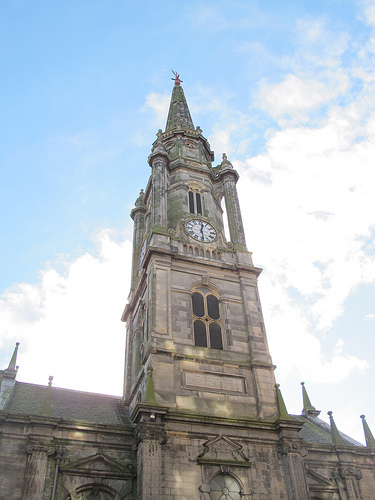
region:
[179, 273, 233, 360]
tower window is black and gold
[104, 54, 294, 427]
Pointy tower on a building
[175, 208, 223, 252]
Clock in front of tower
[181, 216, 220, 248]
Clock is white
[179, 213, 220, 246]
Clock has roman numerals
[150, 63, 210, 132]
Roof of tower is triangular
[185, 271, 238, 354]
Window in front of tower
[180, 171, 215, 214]
Window over clock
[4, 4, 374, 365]
Sky is blue with white clouds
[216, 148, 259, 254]
Column on right side of tower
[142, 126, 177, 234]
Column on left side of tower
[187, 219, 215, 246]
the tower has a clock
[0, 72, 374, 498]
the building is brown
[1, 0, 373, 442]
the sky is blue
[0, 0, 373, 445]
the clouds are white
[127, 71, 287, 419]
the tower is tall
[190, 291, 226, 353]
the tower has windows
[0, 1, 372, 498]
the scene takes place outdoors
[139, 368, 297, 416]
the building has moss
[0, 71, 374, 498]
the building has many details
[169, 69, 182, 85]
a statue on top of the tower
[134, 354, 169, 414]
dark green decorative spire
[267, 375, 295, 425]
dark green decorative spire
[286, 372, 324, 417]
dark green decorative spire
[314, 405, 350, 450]
dark green decorative spire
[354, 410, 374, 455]
dark green decorative spire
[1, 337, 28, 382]
dark green decorative spire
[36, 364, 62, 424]
dark green decorative spire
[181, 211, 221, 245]
white clock with black hands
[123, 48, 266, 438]
Large tower with clock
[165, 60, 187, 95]
red metal weathervane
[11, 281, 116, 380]
clouds are white and bright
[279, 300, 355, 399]
clouds are white and bright